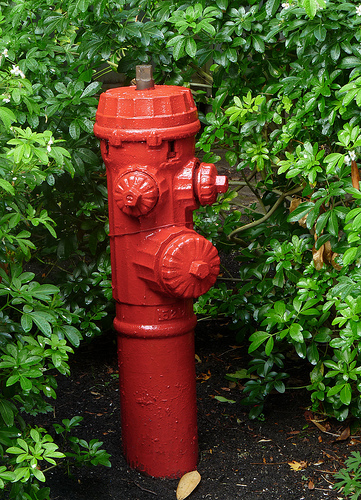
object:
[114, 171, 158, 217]
cover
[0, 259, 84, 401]
leaves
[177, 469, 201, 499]
leaf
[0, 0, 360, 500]
bushes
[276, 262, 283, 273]
leaf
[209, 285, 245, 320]
leaf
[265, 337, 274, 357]
leaf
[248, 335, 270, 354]
leaf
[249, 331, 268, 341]
leaf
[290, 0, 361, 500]
bush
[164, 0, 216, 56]
leaves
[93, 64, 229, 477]
fire hydrant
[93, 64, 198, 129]
top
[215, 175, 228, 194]
knob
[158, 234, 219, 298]
cover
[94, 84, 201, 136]
cover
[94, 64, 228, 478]
black pants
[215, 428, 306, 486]
soil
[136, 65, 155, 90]
knob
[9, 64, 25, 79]
flowers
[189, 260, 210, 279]
knob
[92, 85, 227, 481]
red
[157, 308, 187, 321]
number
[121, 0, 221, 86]
bush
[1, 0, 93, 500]
bush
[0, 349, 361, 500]
ground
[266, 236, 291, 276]
leaf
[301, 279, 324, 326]
leaf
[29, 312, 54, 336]
leaf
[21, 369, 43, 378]
leaf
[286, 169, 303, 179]
leaf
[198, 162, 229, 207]
cover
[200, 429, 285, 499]
dirt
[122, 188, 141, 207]
knob